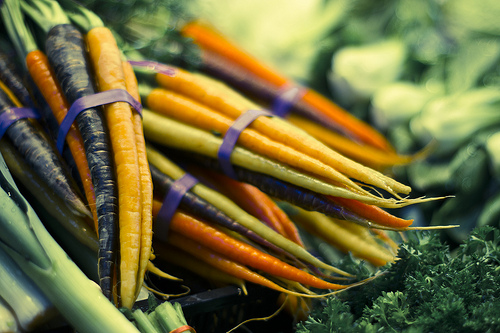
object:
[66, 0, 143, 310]
carror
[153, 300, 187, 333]
vegetable stalk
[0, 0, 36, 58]
root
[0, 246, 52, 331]
onions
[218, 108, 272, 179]
band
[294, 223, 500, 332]
parsley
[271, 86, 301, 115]
rubber band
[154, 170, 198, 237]
rubber band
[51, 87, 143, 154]
rubber band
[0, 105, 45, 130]
rubber band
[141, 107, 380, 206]
carrot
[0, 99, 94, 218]
carrot